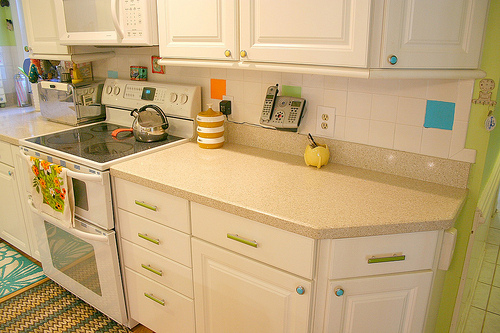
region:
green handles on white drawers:
[113, 180, 193, 332]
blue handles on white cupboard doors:
[254, 260, 387, 332]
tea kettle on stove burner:
[116, 87, 195, 149]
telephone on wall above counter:
[237, 78, 341, 170]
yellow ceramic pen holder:
[287, 122, 348, 189]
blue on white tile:
[404, 85, 489, 175]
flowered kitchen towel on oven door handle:
[19, 136, 133, 330]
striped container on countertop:
[187, 98, 241, 163]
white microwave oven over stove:
[47, 4, 192, 181]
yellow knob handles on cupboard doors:
[199, 0, 319, 82]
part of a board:
[338, 17, 378, 69]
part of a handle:
[291, 273, 302, 304]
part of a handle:
[240, 228, 258, 256]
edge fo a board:
[218, 260, 238, 286]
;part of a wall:
[327, 112, 369, 202]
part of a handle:
[227, 216, 255, 284]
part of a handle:
[144, 197, 156, 212]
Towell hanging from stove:
[24, 159, 76, 222]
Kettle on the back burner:
[126, 99, 167, 144]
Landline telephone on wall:
[254, 79, 307, 133]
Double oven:
[26, 156, 130, 327]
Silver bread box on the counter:
[35, 75, 107, 125]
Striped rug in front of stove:
[0, 269, 125, 331]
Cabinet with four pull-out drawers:
[111, 171, 197, 331]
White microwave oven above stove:
[56, 0, 157, 47]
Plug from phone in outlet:
[217, 94, 234, 119]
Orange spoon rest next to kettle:
[109, 125, 139, 139]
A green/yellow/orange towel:
[18, 155, 78, 232]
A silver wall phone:
[245, 80, 310, 135]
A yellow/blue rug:
[0, 275, 135, 325]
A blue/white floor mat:
[0, 235, 50, 300]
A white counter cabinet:
[185, 230, 315, 330]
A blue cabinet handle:
[290, 280, 310, 295]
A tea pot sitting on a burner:
[120, 100, 170, 145]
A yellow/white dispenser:
[190, 95, 230, 150]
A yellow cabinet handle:
[220, 45, 235, 57]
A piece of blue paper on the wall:
[416, 95, 459, 136]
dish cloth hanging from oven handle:
[23, 152, 79, 223]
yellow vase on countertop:
[303, 142, 331, 168]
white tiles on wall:
[99, 59, 471, 150]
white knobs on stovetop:
[101, 84, 187, 106]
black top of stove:
[34, 124, 163, 157]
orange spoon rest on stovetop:
[109, 132, 131, 137]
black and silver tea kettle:
[127, 102, 173, 142]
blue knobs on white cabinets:
[295, 284, 345, 296]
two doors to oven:
[14, 149, 124, 322]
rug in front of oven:
[6, 272, 136, 331]